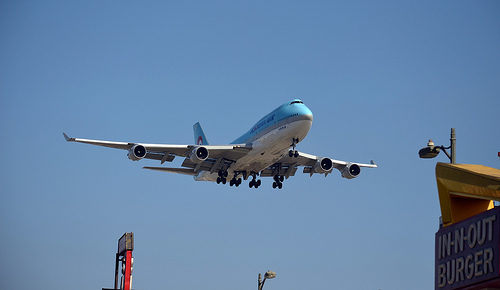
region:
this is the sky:
[166, 8, 337, 73]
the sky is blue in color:
[329, 37, 389, 87]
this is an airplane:
[56, 105, 377, 195]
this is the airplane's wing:
[55, 132, 248, 174]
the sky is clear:
[28, 3, 220, 99]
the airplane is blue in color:
[273, 110, 285, 118]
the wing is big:
[52, 118, 245, 170]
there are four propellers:
[129, 142, 364, 179]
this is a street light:
[419, 139, 451, 159]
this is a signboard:
[435, 228, 496, 261]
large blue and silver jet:
[44, 72, 408, 203]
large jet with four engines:
[93, 130, 380, 208]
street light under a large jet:
[236, 256, 301, 286]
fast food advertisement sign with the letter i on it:
[427, 176, 497, 288]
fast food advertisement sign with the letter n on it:
[427, 211, 492, 286]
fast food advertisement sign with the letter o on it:
[418, 201, 495, 288]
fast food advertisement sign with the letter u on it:
[426, 206, 495, 285]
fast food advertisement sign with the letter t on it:
[436, 211, 498, 288]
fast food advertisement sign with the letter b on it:
[431, 211, 491, 289]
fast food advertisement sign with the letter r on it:
[430, 206, 493, 288]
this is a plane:
[66, 97, 390, 192]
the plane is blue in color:
[279, 102, 291, 116]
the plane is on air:
[48, 91, 397, 204]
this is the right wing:
[49, 120, 185, 172]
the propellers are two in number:
[127, 141, 208, 156]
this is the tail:
[188, 121, 211, 138]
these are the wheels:
[215, 175, 285, 186]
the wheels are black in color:
[220, 170, 287, 190]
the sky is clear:
[360, 13, 447, 93]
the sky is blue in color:
[191, 16, 311, 96]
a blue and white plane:
[78, 70, 396, 224]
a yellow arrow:
[419, 155, 490, 206]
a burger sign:
[409, 157, 495, 268]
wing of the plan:
[63, 122, 229, 168]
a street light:
[242, 252, 280, 287]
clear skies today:
[71, 18, 383, 76]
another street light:
[422, 122, 464, 163]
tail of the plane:
[177, 115, 213, 142]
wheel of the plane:
[273, 180, 285, 195]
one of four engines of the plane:
[314, 149, 335, 180]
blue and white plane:
[67, 73, 367, 242]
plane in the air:
[108, 28, 365, 238]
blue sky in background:
[69, 28, 167, 88]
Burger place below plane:
[411, 213, 498, 278]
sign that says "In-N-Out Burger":
[415, 211, 498, 283]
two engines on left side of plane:
[309, 147, 368, 201]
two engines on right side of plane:
[101, 122, 223, 188]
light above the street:
[400, 118, 470, 170]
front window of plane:
[283, 86, 313, 121]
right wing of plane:
[72, 118, 224, 192]